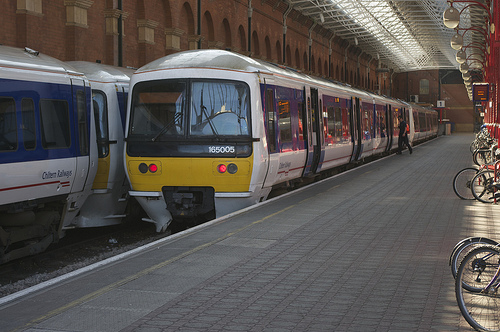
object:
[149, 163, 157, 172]
light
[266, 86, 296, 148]
window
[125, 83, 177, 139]
window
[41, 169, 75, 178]
letters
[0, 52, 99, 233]
train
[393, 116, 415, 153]
person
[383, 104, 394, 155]
doors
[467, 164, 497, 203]
bikes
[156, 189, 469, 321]
ground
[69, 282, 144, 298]
paint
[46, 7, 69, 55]
brick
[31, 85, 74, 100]
paint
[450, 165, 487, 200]
tire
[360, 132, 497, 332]
platform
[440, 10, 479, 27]
skylights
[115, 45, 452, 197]
trains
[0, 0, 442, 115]
wall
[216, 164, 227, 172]
lights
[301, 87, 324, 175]
door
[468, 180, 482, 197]
spokes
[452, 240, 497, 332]
bicycle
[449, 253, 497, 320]
wheel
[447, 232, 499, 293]
bicycles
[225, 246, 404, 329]
gray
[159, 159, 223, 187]
yellow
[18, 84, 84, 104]
blue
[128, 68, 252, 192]
front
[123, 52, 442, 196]
train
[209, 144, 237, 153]
numbers